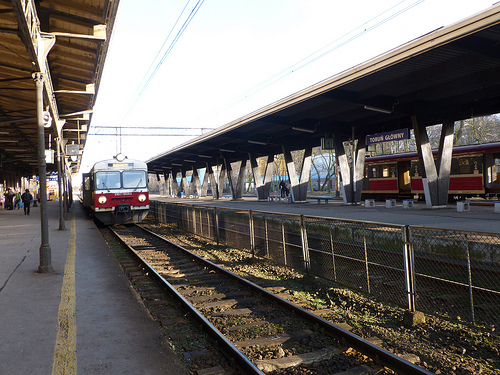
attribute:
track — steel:
[104, 220, 432, 374]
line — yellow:
[53, 205, 92, 373]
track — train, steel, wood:
[122, 224, 334, 364]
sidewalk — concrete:
[6, 208, 111, 370]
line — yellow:
[51, 207, 78, 373]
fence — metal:
[147, 194, 498, 338]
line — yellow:
[53, 197, 76, 373]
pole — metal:
[27, 61, 67, 287]